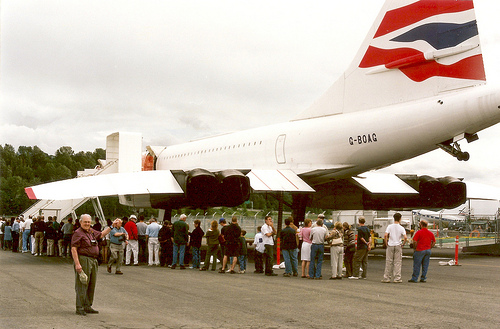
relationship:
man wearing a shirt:
[408, 216, 438, 279] [410, 225, 437, 253]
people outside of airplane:
[1, 212, 437, 316] [27, 0, 498, 215]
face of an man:
[73, 208, 103, 232] [58, 207, 119, 320]